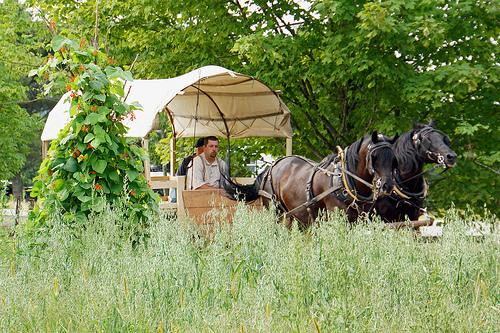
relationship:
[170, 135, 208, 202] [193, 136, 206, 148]
man wears hat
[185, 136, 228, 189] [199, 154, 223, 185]
man wears suspenders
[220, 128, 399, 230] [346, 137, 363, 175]
horse has hair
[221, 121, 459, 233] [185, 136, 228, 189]
horses before men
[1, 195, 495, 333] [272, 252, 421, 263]
grass covering hooves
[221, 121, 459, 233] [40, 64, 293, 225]
horses pull wagon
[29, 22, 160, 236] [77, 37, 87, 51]
plant has flowers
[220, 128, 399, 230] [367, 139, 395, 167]
horse has halter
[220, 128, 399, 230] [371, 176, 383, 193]
horse has bit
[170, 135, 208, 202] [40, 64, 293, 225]
man in wagon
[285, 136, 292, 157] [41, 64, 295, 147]
wood holds canopy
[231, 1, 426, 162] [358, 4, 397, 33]
tree has leaves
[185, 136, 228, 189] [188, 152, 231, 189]
man wears shirt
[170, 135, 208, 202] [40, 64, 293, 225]
man rides wagon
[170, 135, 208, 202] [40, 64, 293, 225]
man in carriage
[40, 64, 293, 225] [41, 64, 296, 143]
carriage has roof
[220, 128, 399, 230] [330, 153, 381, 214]
horse has harness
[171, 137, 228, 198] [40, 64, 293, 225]
people in wagon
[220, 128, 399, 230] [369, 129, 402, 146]
horse has ears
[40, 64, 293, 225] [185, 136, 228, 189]
wagon has passengers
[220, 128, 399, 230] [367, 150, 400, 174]
horse has blinder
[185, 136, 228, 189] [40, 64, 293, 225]
man drives wagon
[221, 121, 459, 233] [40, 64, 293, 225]
horses attached wagon